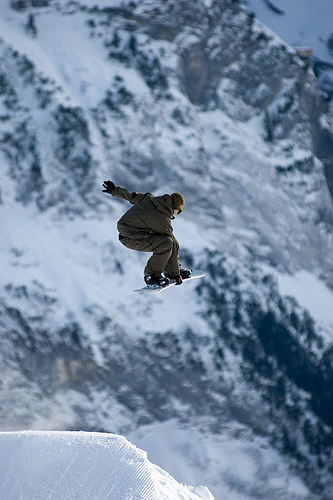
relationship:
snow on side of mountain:
[0, 4, 330, 500] [0, 0, 331, 499]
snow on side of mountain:
[0, 4, 330, 500] [0, 418, 219, 497]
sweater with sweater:
[110, 182, 189, 259] [111, 187, 181, 276]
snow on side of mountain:
[4, 4, 329, 416] [0, 0, 331, 499]